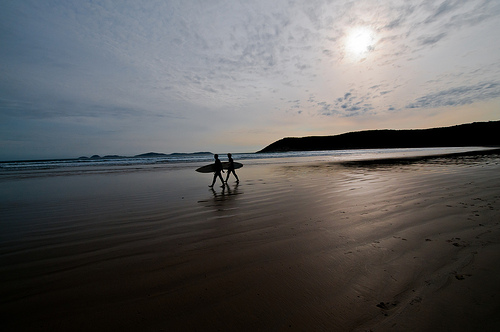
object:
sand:
[44, 186, 433, 289]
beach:
[0, 147, 499, 330]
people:
[196, 152, 245, 188]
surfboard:
[194, 162, 243, 174]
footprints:
[196, 194, 232, 213]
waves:
[32, 159, 109, 172]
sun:
[339, 27, 382, 54]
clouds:
[260, 9, 487, 80]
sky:
[43, 26, 420, 150]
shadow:
[185, 187, 242, 217]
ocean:
[0, 154, 354, 168]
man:
[196, 154, 225, 188]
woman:
[222, 152, 244, 183]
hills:
[256, 120, 500, 153]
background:
[0, 0, 500, 160]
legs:
[208, 170, 241, 187]